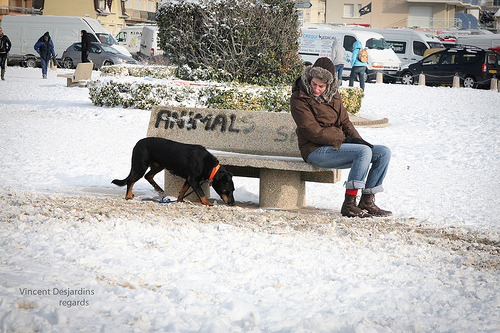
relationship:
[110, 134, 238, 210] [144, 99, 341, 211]
dog by bench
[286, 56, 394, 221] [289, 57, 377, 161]
woman wearing jacket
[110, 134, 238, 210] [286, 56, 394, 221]
dog with woman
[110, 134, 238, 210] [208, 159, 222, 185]
dog wearing collar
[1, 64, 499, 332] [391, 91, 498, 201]
ground covered with snow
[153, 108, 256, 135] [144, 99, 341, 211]
graffiti on bench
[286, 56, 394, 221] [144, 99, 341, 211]
woman on bench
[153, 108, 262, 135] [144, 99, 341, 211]
graffiti on bench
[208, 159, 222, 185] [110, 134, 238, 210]
collar on dog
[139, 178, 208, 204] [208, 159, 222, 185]
leash attached to collar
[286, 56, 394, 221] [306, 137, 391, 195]
woman wearing jeans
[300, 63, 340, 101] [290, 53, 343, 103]
fur around hood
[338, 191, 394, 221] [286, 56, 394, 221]
boots on woman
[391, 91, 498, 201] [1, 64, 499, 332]
snow on ground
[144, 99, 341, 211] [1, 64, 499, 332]
bench on ground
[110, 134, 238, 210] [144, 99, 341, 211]
dog sniffing by bench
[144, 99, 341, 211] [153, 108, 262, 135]
bench says graffiti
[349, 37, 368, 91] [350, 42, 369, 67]
woman wearing coat